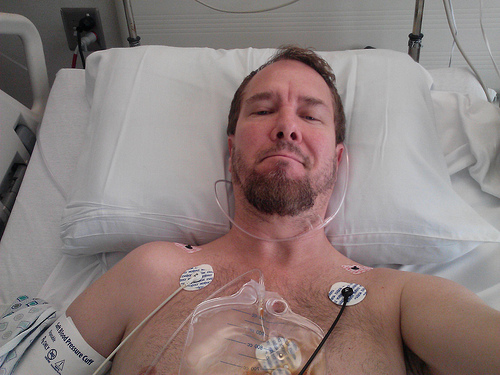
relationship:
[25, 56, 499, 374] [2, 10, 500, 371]
man on hospital bed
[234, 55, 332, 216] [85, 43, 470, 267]
head on pillow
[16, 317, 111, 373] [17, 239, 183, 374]
blood pressure cuff on arm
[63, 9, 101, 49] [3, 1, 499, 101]
outlet on wall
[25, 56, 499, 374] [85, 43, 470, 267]
man on pillow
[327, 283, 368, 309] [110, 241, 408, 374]
medical patch on chest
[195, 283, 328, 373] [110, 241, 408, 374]
medical bag on chest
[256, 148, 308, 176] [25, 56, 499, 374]
mouth of man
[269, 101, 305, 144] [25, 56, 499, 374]
nose of man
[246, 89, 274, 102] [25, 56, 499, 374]
eyebrow of man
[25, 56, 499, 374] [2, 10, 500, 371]
man laying on hospital bed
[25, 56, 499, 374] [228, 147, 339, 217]
man has beard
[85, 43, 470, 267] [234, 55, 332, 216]
pillow underneath head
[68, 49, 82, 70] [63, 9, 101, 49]
cord plugged into outlet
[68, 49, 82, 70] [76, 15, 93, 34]
cord under cord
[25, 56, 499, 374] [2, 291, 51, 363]
man wearing hospital gown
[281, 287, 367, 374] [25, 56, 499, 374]
wire attached to man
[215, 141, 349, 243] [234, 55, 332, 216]
wire on head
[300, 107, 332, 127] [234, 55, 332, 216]
eye on head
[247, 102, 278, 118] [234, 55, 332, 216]
eye on head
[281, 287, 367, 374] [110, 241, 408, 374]
wire on chest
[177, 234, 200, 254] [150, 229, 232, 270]
wire on shoulder